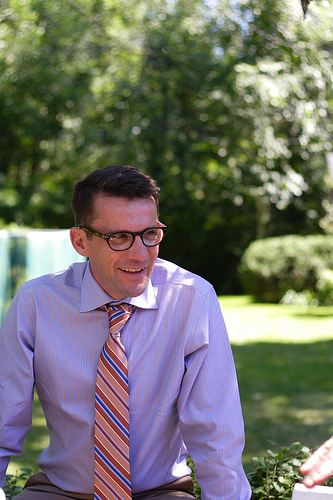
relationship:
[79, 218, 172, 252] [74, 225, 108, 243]
glasses with frame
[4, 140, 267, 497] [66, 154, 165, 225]
man with hair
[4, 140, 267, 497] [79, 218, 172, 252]
man with glasses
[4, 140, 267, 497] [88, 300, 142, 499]
man wearing tie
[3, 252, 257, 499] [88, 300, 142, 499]
dress shirt with tie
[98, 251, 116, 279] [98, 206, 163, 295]
wrinkles on face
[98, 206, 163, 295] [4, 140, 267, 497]
face of man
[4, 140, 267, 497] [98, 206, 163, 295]
man with face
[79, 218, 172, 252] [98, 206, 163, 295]
glasses on face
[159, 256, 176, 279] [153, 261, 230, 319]
reflection on shoulder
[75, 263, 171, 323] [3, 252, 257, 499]
collar on dress shirt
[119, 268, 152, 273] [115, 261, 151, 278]
teeth in mouth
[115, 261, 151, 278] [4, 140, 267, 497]
mouth of man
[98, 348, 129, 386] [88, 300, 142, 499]
stripe on tie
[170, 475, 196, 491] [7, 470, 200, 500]
pocket on pants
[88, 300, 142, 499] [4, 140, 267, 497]
tie of man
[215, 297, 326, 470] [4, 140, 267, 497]
grass behind man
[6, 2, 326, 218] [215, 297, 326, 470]
trees beyond grass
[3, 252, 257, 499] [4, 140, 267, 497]
dress shirt of man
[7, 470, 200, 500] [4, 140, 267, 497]
pants of man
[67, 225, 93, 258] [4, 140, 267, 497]
ear of man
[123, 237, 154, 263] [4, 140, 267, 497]
nose of man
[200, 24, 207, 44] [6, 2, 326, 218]
leaf of trees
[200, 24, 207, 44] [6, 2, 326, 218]
leaf on trees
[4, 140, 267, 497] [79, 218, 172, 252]
man wearing glasses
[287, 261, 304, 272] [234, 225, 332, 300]
leaves from bushes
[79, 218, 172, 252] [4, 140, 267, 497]
glasses on man